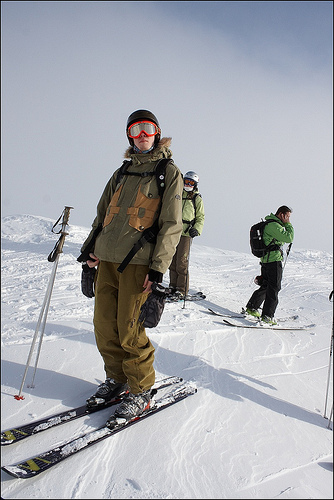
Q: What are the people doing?
A: Skiing.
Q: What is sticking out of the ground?
A: Ski poles.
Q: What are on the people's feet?
A: Skis.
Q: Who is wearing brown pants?
A: Nearest man.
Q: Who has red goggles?
A: Nearest man.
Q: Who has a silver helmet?
A: Person in green jacket and brown pants.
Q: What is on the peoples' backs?
A: Backpacks.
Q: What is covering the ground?
A: Snow.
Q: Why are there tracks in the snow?
A: Skis.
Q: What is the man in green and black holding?
A: Phone.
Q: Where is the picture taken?
A: On a mountain.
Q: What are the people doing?
A: Skiing.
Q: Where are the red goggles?
A: On the man's face.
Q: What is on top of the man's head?
A: A helmut.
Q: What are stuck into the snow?
A: Poles.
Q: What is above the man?
A: The sky.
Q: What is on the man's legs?
A: Ski pants.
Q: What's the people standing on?
A: Snow.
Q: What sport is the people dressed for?
A: Skiing.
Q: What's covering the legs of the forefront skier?
A: Pants.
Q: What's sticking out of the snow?
A: Ski poles.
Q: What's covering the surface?
A: Snow.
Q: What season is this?
A: Winter.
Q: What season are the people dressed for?
A: Winter.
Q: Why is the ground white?
A: Its covered in snow.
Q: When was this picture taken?
A: During the day.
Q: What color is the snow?
A: White.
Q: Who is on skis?
A: The man.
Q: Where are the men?
A: On a ski slope.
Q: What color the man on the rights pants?
A: Brown.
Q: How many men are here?
A: Three.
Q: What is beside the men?
A: Ski poles.